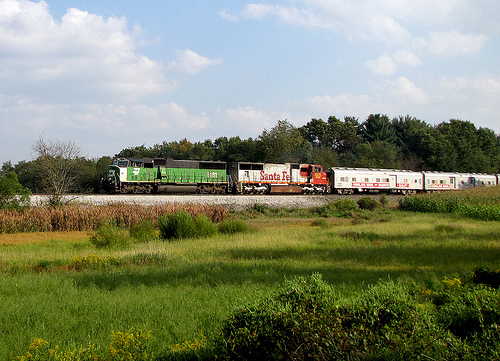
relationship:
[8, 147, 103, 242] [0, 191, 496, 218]
big bushes on side of tracks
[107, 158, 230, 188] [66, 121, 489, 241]
engine of train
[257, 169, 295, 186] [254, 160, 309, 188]
santa fe on train car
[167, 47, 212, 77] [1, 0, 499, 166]
cloud in sky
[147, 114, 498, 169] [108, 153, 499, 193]
green trees behind trains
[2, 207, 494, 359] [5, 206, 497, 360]
grass in field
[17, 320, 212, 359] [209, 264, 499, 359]
yellow flowers by bushes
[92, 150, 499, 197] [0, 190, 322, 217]
train on track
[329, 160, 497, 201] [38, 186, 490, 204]
train cars on track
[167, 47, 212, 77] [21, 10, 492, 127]
cloud in sky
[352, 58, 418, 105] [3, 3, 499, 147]
white clouds in sky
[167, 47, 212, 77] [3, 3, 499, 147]
cloud in sky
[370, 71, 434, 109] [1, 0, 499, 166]
cloud in sky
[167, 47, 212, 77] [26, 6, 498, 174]
cloud in sky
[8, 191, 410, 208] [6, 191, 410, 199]
gravel beside track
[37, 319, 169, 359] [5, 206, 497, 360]
flower in field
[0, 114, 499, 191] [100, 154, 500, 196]
trees growing on side of train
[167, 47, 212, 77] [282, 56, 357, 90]
cloud in sky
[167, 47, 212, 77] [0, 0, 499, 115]
cloud in sky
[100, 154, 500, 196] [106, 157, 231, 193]
train on truck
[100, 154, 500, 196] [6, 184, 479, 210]
train on track